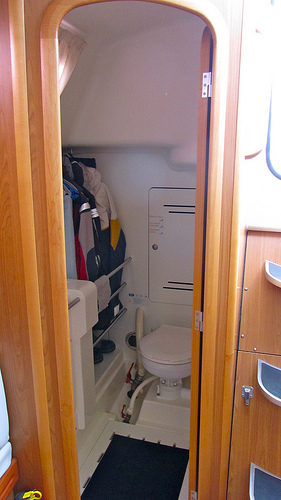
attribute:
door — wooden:
[182, 26, 214, 492]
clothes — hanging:
[63, 162, 127, 311]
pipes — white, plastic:
[123, 301, 152, 423]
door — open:
[35, 0, 216, 493]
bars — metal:
[93, 252, 128, 343]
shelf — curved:
[253, 356, 280, 410]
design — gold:
[109, 219, 120, 247]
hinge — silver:
[202, 73, 210, 95]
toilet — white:
[139, 310, 191, 403]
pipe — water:
[131, 311, 146, 380]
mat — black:
[85, 430, 186, 498]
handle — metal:
[239, 383, 253, 408]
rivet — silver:
[242, 283, 248, 294]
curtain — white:
[56, 33, 87, 96]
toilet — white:
[135, 320, 192, 403]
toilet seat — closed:
[138, 322, 193, 364]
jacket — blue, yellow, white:
[75, 160, 126, 292]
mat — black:
[76, 433, 192, 497]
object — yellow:
[23, 489, 43, 498]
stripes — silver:
[78, 199, 89, 211]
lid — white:
[136, 322, 193, 366]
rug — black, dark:
[80, 432, 189, 498]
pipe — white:
[133, 307, 150, 376]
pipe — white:
[125, 376, 158, 416]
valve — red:
[117, 402, 125, 417]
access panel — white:
[148, 187, 196, 305]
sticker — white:
[126, 291, 148, 306]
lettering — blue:
[129, 296, 145, 304]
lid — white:
[137, 322, 193, 361]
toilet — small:
[137, 323, 193, 400]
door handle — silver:
[240, 384, 254, 405]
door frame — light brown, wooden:
[39, 1, 80, 498]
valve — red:
[124, 361, 135, 383]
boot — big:
[92, 346, 103, 363]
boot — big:
[92, 333, 114, 353]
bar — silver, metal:
[95, 256, 132, 288]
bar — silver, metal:
[98, 281, 127, 312]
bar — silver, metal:
[93, 307, 126, 346]